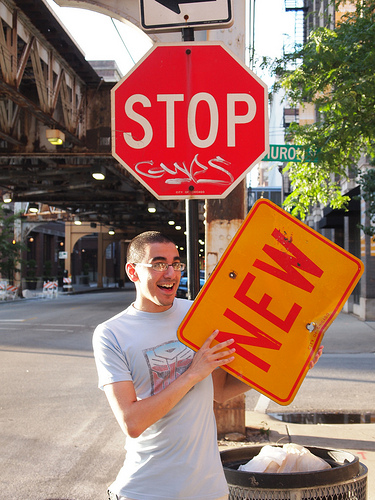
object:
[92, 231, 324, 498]
man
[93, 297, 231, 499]
shirt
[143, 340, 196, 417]
transformer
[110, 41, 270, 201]
sign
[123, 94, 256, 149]
stop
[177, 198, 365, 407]
sign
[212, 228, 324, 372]
new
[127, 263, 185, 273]
glasses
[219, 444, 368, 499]
metal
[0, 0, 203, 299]
bridge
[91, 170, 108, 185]
lights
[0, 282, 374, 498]
road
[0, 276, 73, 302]
barricades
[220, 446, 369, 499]
trash can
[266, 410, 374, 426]
water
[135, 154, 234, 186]
graffiti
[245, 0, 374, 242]
tree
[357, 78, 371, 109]
leaves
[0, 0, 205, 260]
beams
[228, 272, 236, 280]
hole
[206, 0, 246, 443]
post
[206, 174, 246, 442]
rust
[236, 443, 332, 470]
trash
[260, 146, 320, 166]
sign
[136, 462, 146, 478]
white